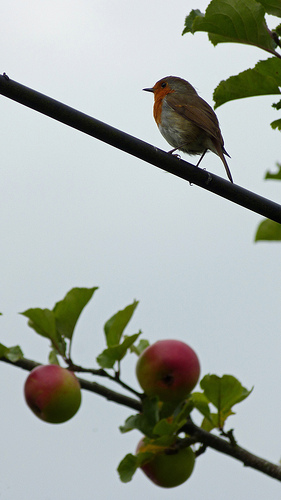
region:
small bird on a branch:
[134, 74, 231, 183]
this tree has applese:
[26, 323, 198, 497]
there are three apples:
[11, 340, 212, 487]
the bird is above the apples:
[99, 65, 226, 464]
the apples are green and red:
[31, 338, 216, 484]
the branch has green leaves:
[7, 283, 139, 373]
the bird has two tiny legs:
[161, 136, 213, 174]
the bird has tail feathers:
[217, 143, 237, 184]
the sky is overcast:
[26, 186, 228, 298]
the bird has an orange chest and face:
[144, 79, 174, 120]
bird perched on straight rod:
[24, 68, 259, 200]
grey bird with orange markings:
[135, 53, 239, 195]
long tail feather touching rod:
[194, 137, 245, 187]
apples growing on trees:
[19, 308, 214, 479]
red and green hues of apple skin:
[15, 360, 87, 419]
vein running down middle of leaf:
[196, 359, 246, 432]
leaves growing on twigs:
[93, 299, 127, 383]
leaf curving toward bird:
[130, 49, 270, 155]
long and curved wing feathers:
[161, 84, 234, 151]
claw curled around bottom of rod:
[185, 143, 207, 195]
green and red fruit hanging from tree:
[128, 430, 201, 499]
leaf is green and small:
[194, 371, 251, 435]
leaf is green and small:
[123, 389, 187, 442]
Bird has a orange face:
[133, 60, 249, 198]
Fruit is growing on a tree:
[28, 317, 237, 485]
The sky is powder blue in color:
[2, 17, 274, 325]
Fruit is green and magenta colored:
[8, 325, 250, 482]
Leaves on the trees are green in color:
[181, 2, 277, 115]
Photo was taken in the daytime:
[10, 21, 277, 423]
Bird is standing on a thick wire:
[16, 56, 264, 212]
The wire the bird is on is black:
[56, 86, 276, 220]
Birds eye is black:
[154, 80, 174, 91]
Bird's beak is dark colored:
[135, 73, 157, 99]